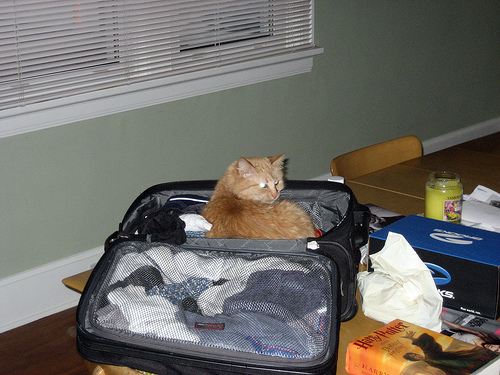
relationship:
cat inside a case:
[205, 155, 323, 242] [73, 179, 366, 375]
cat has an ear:
[205, 155, 323, 242] [236, 155, 256, 175]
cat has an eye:
[205, 155, 323, 242] [261, 182, 268, 189]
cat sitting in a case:
[205, 155, 323, 242] [73, 179, 366, 375]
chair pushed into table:
[327, 133, 427, 182] [1, 129, 499, 375]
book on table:
[344, 319, 500, 375] [1, 129, 499, 375]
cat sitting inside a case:
[205, 155, 323, 242] [73, 179, 366, 375]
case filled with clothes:
[73, 179, 366, 375] [93, 243, 334, 359]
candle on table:
[424, 168, 465, 224] [1, 129, 499, 375]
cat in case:
[205, 155, 323, 242] [73, 179, 366, 375]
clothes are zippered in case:
[93, 243, 334, 359] [73, 179, 366, 375]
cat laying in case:
[205, 155, 323, 242] [73, 179, 366, 375]